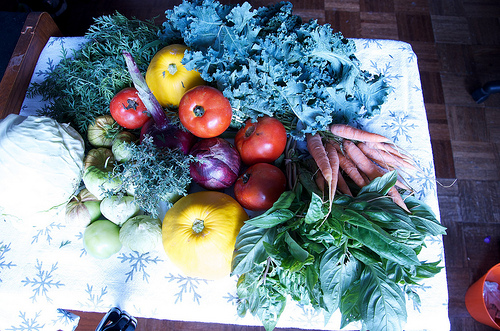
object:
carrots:
[294, 123, 419, 216]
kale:
[154, 0, 391, 145]